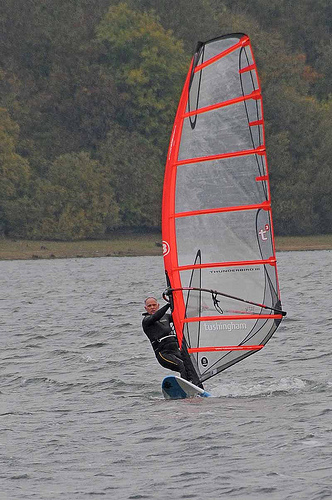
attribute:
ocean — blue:
[0, 247, 330, 498]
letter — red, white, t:
[258, 227, 267, 241]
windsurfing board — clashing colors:
[154, 27, 291, 401]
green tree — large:
[38, 160, 127, 220]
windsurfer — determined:
[125, 33, 288, 401]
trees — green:
[2, 1, 331, 240]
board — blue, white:
[160, 367, 214, 403]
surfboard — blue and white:
[158, 372, 216, 400]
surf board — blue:
[160, 375, 209, 402]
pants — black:
[153, 347, 203, 382]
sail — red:
[155, 22, 293, 383]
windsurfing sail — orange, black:
[163, 30, 292, 381]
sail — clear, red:
[160, 31, 287, 384]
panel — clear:
[174, 150, 268, 215]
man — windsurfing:
[139, 291, 201, 389]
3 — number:
[264, 223, 270, 229]